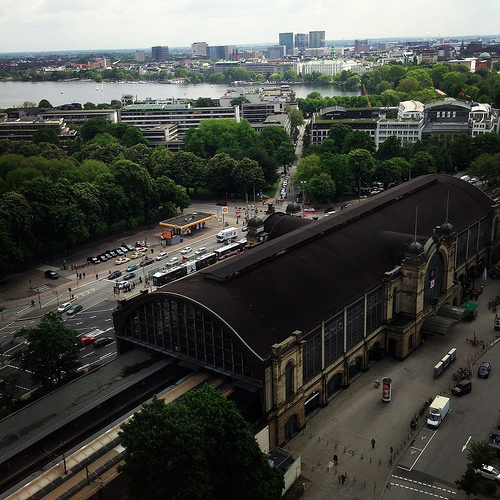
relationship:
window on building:
[183, 320, 198, 340] [108, 165, 497, 456]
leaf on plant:
[132, 167, 137, 187] [101, 156, 175, 228]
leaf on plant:
[102, 167, 112, 173] [86, 162, 140, 228]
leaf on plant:
[117, 127, 124, 131] [70, 115, 148, 142]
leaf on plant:
[109, 125, 115, 131] [117, 123, 151, 157]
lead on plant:
[133, 167, 135, 170] [204, 155, 236, 200]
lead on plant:
[102, 181, 104, 183] [231, 158, 266, 198]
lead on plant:
[90, 167, 95, 172] [113, 160, 152, 215]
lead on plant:
[220, 162, 222, 165] [80, 156, 110, 182]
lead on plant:
[243, 171, 246, 175] [94, 172, 128, 230]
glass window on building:
[169, 301, 184, 328] [108, 165, 497, 456]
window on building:
[183, 301, 193, 320] [108, 165, 497, 456]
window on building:
[198, 351, 211, 372] [108, 165, 497, 456]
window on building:
[204, 352, 216, 367] [108, 165, 497, 456]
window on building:
[132, 312, 141, 324] [106, 166, 494, 428]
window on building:
[365, 286, 381, 341] [8, 168, 499, 495]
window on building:
[344, 297, 365, 349] [8, 168, 499, 495]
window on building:
[298, 329, 323, 388] [8, 168, 499, 495]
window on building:
[456, 228, 471, 264] [8, 168, 499, 495]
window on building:
[475, 219, 490, 252] [8, 168, 499, 495]